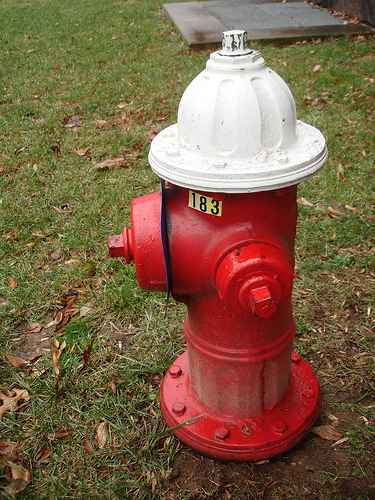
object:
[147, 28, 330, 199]
top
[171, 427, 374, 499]
dirt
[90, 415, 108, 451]
leaves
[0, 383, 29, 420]
leaves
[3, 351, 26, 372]
leaves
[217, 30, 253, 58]
top part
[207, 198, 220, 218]
numbers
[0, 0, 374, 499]
grass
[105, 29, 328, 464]
fire hydrant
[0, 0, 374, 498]
ground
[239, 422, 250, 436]
chip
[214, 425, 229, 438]
red bolt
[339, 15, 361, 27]
leaves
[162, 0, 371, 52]
slab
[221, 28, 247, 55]
bolt